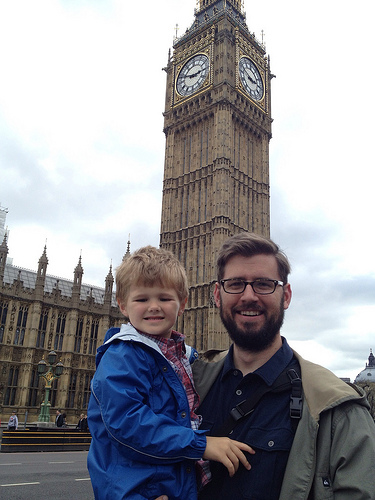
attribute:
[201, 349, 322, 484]
shirt — dark blue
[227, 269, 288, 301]
glasses — black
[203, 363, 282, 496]
shirt — blue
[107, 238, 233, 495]
boy — little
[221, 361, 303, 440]
straps — black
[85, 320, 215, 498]
coat — blue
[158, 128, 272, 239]
wall — brown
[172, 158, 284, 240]
wall — brown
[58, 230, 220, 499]
boy — young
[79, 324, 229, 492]
jacket — blue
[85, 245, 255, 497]
boy — young